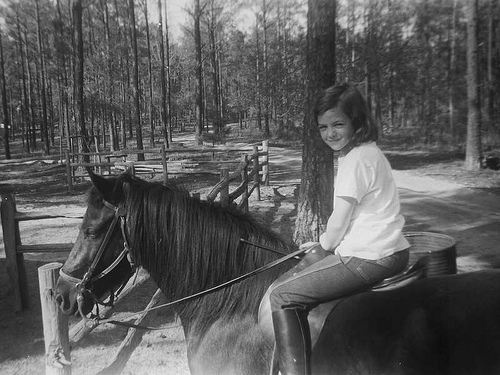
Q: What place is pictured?
A: It is a road.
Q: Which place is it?
A: It is a road.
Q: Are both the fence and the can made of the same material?
A: No, the fence is made of wood and the can is made of metal.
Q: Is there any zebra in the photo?
A: No, there are no zebras.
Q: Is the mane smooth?
A: Yes, the mane is smooth.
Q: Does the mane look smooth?
A: Yes, the mane is smooth.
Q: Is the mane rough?
A: No, the mane is smooth.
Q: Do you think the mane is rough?
A: No, the mane is smooth.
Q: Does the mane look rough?
A: No, the mane is smooth.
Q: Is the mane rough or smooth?
A: The mane is smooth.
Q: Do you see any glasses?
A: No, there are no glasses.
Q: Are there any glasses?
A: No, there are no glasses.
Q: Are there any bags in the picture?
A: No, there are no bags.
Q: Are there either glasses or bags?
A: No, there are no bags or glasses.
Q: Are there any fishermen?
A: No, there are no fishermen.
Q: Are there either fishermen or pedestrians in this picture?
A: No, there are no fishermen or pedestrians.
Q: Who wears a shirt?
A: The girl wears a shirt.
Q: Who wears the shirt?
A: The girl wears a shirt.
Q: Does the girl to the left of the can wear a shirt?
A: Yes, the girl wears a shirt.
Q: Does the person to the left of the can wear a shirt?
A: Yes, the girl wears a shirt.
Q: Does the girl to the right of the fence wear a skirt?
A: No, the girl wears a shirt.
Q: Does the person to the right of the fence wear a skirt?
A: No, the girl wears a shirt.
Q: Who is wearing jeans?
A: The girl is wearing jeans.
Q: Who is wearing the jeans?
A: The girl is wearing jeans.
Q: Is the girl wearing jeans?
A: Yes, the girl is wearing jeans.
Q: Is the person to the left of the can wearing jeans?
A: Yes, the girl is wearing jeans.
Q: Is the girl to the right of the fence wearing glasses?
A: No, the girl is wearing jeans.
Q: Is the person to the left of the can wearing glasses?
A: No, the girl is wearing jeans.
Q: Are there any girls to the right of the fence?
A: Yes, there is a girl to the right of the fence.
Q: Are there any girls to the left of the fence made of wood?
A: No, the girl is to the right of the fence.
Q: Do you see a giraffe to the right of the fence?
A: No, there is a girl to the right of the fence.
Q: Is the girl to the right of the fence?
A: Yes, the girl is to the right of the fence.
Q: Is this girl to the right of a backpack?
A: No, the girl is to the right of the fence.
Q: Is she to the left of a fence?
A: No, the girl is to the right of a fence.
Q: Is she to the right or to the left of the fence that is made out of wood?
A: The girl is to the right of the fence.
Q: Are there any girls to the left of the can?
A: Yes, there is a girl to the left of the can.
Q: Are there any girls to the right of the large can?
A: No, the girl is to the left of the can.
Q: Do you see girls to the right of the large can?
A: No, the girl is to the left of the can.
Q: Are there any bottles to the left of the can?
A: No, there is a girl to the left of the can.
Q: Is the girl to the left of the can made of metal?
A: Yes, the girl is to the left of the can.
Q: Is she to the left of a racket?
A: No, the girl is to the left of the can.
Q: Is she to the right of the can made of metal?
A: No, the girl is to the left of the can.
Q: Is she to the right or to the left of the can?
A: The girl is to the left of the can.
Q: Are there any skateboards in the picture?
A: No, there are no skateboards.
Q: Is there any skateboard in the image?
A: No, there are no skateboards.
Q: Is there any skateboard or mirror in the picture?
A: No, there are no skateboards or mirrors.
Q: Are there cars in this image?
A: No, there are no cars.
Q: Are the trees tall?
A: Yes, the trees are tall.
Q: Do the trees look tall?
A: Yes, the trees are tall.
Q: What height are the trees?
A: The trees are tall.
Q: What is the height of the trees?
A: The trees are tall.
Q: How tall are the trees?
A: The trees are tall.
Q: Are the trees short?
A: No, the trees are tall.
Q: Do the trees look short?
A: No, the trees are tall.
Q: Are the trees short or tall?
A: The trees are tall.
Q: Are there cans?
A: Yes, there is a can.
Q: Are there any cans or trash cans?
A: Yes, there is a can.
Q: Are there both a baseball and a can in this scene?
A: No, there is a can but no baseballs.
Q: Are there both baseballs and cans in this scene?
A: No, there is a can but no baseballs.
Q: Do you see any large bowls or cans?
A: Yes, there is a large can.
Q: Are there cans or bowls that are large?
A: Yes, the can is large.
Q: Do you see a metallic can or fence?
A: Yes, there is a metal can.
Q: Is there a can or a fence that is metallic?
A: Yes, the can is metallic.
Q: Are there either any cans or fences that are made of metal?
A: Yes, the can is made of metal.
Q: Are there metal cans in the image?
A: Yes, there is a metal can.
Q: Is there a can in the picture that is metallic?
A: Yes, there is a can that is metallic.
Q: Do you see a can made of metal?
A: Yes, there is a can that is made of metal.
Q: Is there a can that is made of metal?
A: Yes, there is a can that is made of metal.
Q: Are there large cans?
A: Yes, there is a large can.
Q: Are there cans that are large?
A: Yes, there is a can that is large.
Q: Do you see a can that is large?
A: Yes, there is a can that is large.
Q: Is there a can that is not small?
A: Yes, there is a large can.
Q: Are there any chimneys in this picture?
A: No, there are no chimneys.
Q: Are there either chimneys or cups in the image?
A: No, there are no chimneys or cups.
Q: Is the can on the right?
A: Yes, the can is on the right of the image.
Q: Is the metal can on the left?
A: No, the can is on the right of the image.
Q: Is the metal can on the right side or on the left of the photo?
A: The can is on the right of the image.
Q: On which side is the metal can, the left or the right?
A: The can is on the right of the image.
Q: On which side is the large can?
A: The can is on the right of the image.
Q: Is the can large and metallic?
A: Yes, the can is large and metallic.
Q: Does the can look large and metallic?
A: Yes, the can is large and metallic.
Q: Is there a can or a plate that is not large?
A: No, there is a can but it is large.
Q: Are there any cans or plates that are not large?
A: No, there is a can but it is large.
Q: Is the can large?
A: Yes, the can is large.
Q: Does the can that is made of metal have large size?
A: Yes, the can is large.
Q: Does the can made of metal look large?
A: Yes, the can is large.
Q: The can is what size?
A: The can is large.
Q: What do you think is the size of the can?
A: The can is large.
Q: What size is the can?
A: The can is large.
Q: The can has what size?
A: The can is large.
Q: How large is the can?
A: The can is large.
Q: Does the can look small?
A: No, the can is large.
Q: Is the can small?
A: No, the can is large.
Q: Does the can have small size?
A: No, the can is large.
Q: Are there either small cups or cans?
A: No, there is a can but it is large.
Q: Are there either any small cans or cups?
A: No, there is a can but it is large.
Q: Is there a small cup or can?
A: No, there is a can but it is large.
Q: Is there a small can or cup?
A: No, there is a can but it is large.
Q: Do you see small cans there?
A: No, there is a can but it is large.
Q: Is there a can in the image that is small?
A: No, there is a can but it is large.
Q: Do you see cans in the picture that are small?
A: No, there is a can but it is large.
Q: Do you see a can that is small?
A: No, there is a can but it is large.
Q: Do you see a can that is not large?
A: No, there is a can but it is large.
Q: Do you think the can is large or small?
A: The can is large.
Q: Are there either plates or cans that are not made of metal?
A: No, there is a can but it is made of metal.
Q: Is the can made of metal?
A: Yes, the can is made of metal.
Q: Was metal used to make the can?
A: Yes, the can is made of metal.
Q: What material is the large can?
A: The can is made of metal.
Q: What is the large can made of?
A: The can is made of metal.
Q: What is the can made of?
A: The can is made of metal.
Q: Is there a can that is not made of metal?
A: No, there is a can but it is made of metal.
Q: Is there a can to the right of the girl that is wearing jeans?
A: Yes, there is a can to the right of the girl.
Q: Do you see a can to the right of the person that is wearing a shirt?
A: Yes, there is a can to the right of the girl.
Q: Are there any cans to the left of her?
A: No, the can is to the right of the girl.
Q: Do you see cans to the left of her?
A: No, the can is to the right of the girl.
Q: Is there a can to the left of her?
A: No, the can is to the right of the girl.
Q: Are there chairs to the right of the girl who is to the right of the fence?
A: No, there is a can to the right of the girl.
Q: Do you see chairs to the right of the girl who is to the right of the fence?
A: No, there is a can to the right of the girl.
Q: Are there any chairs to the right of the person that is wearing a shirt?
A: No, there is a can to the right of the girl.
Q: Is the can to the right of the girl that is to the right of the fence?
A: Yes, the can is to the right of the girl.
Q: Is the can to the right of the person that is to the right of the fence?
A: Yes, the can is to the right of the girl.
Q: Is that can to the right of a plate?
A: No, the can is to the right of the girl.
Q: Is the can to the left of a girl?
A: No, the can is to the right of a girl.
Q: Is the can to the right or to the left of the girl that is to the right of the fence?
A: The can is to the right of the girl.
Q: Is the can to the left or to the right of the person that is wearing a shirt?
A: The can is to the right of the girl.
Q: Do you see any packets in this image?
A: No, there are no packets.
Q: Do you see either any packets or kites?
A: No, there are no packets or kites.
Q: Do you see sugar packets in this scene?
A: No, there are no sugar packets.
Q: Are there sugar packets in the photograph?
A: No, there are no sugar packets.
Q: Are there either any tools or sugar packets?
A: No, there are no sugar packets or tools.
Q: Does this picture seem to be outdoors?
A: Yes, the picture is outdoors.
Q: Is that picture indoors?
A: No, the picture is outdoors.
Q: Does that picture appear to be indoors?
A: No, the picture is outdoors.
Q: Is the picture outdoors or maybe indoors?
A: The picture is outdoors.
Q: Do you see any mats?
A: No, there are no mats.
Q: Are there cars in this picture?
A: No, there are no cars.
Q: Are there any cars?
A: No, there are no cars.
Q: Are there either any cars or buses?
A: No, there are no cars or buses.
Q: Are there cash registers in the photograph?
A: No, there are no cash registers.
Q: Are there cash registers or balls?
A: No, there are no cash registers or balls.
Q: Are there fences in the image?
A: Yes, there is a fence.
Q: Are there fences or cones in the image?
A: Yes, there is a fence.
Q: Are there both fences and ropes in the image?
A: No, there is a fence but no ropes.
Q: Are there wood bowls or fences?
A: Yes, there is a wood fence.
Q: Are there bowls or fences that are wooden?
A: Yes, the fence is wooden.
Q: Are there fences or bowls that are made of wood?
A: Yes, the fence is made of wood.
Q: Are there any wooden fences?
A: Yes, there is a wood fence.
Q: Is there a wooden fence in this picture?
A: Yes, there is a wood fence.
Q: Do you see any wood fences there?
A: Yes, there is a wood fence.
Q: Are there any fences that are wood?
A: Yes, there is a wood fence.